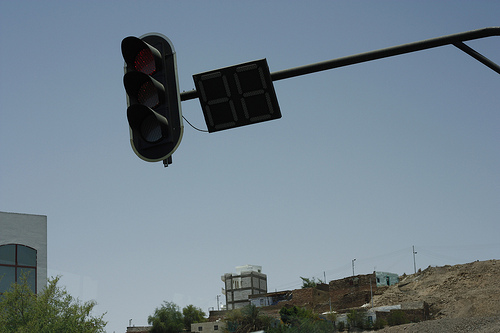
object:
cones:
[119, 32, 185, 169]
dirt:
[410, 316, 481, 330]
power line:
[346, 250, 409, 263]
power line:
[325, 260, 360, 271]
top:
[323, 257, 489, 310]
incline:
[344, 250, 500, 326]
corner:
[39, 214, 48, 299]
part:
[248, 293, 285, 307]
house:
[219, 264, 284, 324]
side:
[1, 215, 18, 230]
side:
[230, 276, 250, 291]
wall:
[228, 278, 254, 291]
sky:
[311, 129, 399, 221]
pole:
[179, 27, 500, 136]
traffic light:
[120, 35, 165, 78]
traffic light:
[122, 72, 166, 108]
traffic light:
[126, 103, 170, 145]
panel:
[138, 32, 185, 169]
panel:
[191, 57, 283, 134]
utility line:
[357, 246, 404, 261]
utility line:
[357, 256, 401, 266]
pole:
[351, 258, 357, 276]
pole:
[412, 245, 418, 274]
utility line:
[413, 245, 463, 255]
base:
[291, 259, 500, 333]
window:
[213, 322, 218, 331]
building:
[191, 320, 233, 333]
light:
[119, 34, 163, 79]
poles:
[412, 245, 418, 273]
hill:
[293, 254, 500, 332]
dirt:
[427, 273, 499, 310]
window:
[0, 243, 38, 297]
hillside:
[187, 270, 449, 332]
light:
[119, 32, 183, 169]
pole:
[180, 27, 500, 102]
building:
[219, 264, 267, 313]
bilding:
[0, 211, 48, 332]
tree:
[0, 267, 107, 332]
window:
[15, 266, 37, 297]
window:
[259, 299, 263, 305]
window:
[214, 325, 219, 331]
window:
[251, 298, 257, 302]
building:
[374, 270, 401, 288]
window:
[377, 277, 381, 283]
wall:
[0, 224, 42, 241]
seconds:
[190, 57, 283, 134]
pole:
[270, 26, 499, 83]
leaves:
[0, 278, 113, 332]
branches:
[146, 299, 207, 332]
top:
[10, 279, 83, 307]